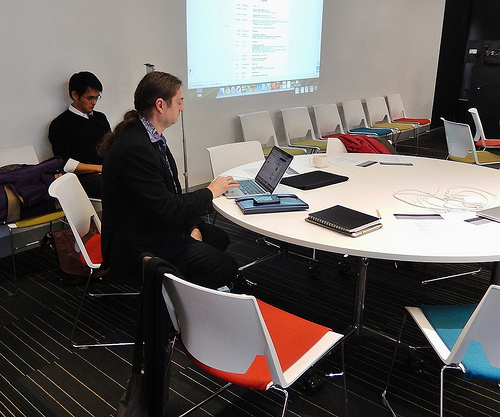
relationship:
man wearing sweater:
[48, 68, 107, 195] [47, 111, 112, 178]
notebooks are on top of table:
[304, 204, 382, 239] [210, 149, 499, 265]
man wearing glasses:
[48, 68, 107, 195] [77, 92, 105, 103]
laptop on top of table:
[222, 145, 295, 199] [210, 149, 499, 265]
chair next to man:
[140, 254, 353, 416] [101, 72, 238, 347]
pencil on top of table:
[375, 206, 384, 225] [210, 149, 499, 265]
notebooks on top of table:
[304, 204, 382, 239] [210, 149, 499, 265]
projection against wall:
[186, 0, 323, 106] [2, 3, 448, 258]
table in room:
[210, 149, 499, 265] [2, 3, 500, 409]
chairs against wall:
[2, 93, 431, 276] [2, 3, 448, 258]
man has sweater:
[48, 68, 107, 195] [47, 111, 112, 178]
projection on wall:
[186, 0, 323, 106] [2, 3, 448, 258]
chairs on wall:
[2, 93, 431, 276] [2, 3, 448, 258]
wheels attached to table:
[299, 375, 324, 395] [210, 149, 499, 265]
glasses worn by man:
[77, 92, 105, 103] [48, 68, 107, 195]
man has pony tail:
[101, 72, 238, 347] [95, 111, 157, 174]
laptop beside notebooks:
[222, 145, 295, 199] [304, 204, 382, 239]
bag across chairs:
[0, 154, 66, 225] [2, 93, 431, 276]